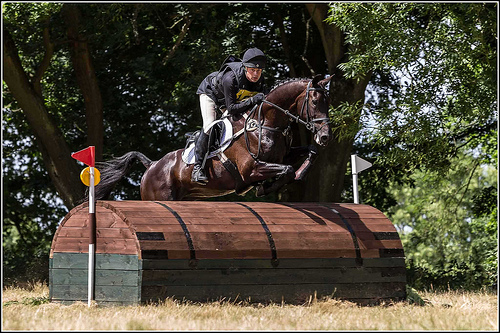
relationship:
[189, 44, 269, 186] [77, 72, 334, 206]
jockey on horse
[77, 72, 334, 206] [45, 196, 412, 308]
horse jumps obstacle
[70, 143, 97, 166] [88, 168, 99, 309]
flag on post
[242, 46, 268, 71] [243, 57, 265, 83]
hat on head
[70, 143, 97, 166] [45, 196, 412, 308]
flag near obstacle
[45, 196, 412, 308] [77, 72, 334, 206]
obstacle jumped by horse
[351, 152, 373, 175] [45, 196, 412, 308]
flag near obstacle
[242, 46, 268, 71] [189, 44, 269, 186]
hat on jockey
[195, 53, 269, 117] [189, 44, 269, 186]
shirt on jockey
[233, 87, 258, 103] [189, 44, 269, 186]
number on jockey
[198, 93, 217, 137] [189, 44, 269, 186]
pants on jockey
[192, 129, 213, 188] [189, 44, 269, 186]
boots on jockey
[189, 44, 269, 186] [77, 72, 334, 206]
jockey rides horse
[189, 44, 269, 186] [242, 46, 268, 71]
jockey wears hat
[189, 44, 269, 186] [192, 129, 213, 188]
jockey wears boots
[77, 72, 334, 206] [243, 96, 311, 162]
horse wears bridle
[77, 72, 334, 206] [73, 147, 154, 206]
horse has tail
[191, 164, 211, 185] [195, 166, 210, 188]
foot in stirrup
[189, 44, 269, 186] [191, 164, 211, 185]
jockey has foot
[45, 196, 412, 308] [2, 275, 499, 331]
obstacle on grass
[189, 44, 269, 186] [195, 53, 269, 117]
jockey wears shirt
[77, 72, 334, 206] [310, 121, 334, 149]
horse has nose